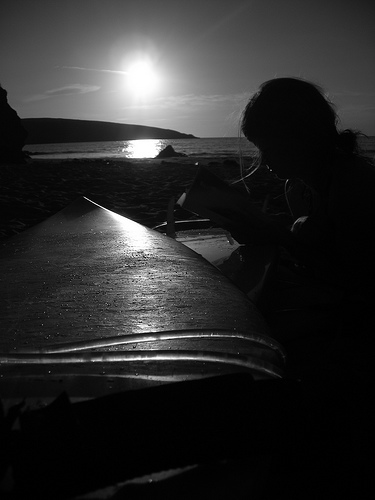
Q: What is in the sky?
A: The moon.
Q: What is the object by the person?
A: A surfboard.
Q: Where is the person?
A: Outside by the water.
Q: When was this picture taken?
A: Sunset.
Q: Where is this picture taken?
A: A boat.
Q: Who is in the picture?
A: A woman.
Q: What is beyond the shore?
A: Water.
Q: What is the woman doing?
A: Leaning.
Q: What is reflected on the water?
A: Sun.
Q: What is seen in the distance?
A: A hill.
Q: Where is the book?
A: Beach.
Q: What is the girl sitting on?
A: Surfboard.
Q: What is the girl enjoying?
A: Beach.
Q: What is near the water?
A: Boat.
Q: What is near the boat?
A: Woman's head.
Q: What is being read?
A: Book.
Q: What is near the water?
A: Rocky beach.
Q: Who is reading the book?
A: The woman.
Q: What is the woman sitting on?
A: Beach.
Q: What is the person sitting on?
A: A boat.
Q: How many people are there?
A: One.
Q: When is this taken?
A: Daytime.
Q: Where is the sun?
A: In the sky.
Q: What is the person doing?
A: Reading a book.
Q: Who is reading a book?
A: The person.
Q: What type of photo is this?
A: Black and white.